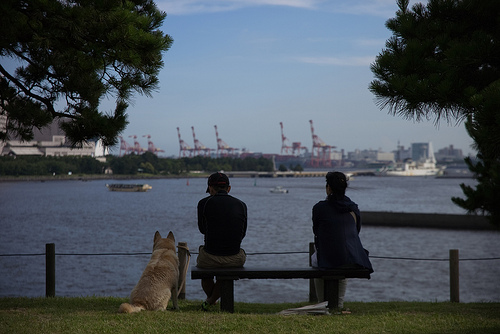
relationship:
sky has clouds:
[0, 0, 479, 158] [96, 2, 479, 160]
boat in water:
[379, 160, 440, 176] [0, 173, 499, 301]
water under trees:
[0, 173, 499, 301] [368, 36, 498, 220]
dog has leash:
[90, 190, 232, 319] [183, 255, 188, 294]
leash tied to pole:
[183, 255, 188, 294] [424, 200, 488, 320]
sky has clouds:
[183, 55, 297, 106] [302, 55, 372, 67]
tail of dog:
[115, 288, 155, 312] [124, 224, 206, 304]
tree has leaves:
[2, 0, 176, 165] [0, 2, 173, 98]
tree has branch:
[2, 0, 176, 165] [0, 62, 105, 131]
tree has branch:
[2, 0, 176, 165] [0, 39, 107, 96]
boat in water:
[384, 161, 441, 176] [0, 173, 499, 301]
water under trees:
[0, 173, 499, 301] [4, 11, 497, 221]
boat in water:
[361, 210, 497, 231] [373, 232, 472, 246]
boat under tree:
[361, 210, 497, 231] [365, 1, 498, 226]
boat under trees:
[379, 160, 440, 176] [0, 1, 175, 183]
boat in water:
[379, 160, 440, 176] [35, 191, 150, 232]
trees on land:
[368, 0, 498, 216] [360, 210, 499, 232]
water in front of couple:
[0, 173, 499, 301] [194, 167, 374, 308]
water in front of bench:
[0, 173, 499, 301] [187, 260, 374, 311]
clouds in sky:
[221, 11, 351, 88] [105, 9, 355, 130]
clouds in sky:
[271, 53, 380, 67] [130, 11, 427, 143]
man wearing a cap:
[198, 173, 242, 267] [186, 154, 235, 201]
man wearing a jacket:
[197, 173, 246, 311] [295, 196, 399, 298]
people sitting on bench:
[310, 171, 370, 267] [195, 272, 371, 306]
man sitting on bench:
[197, 173, 246, 311] [195, 272, 371, 306]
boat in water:
[107, 183, 153, 192] [0, 173, 499, 301]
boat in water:
[2, 96, 108, 163] [0, 173, 499, 301]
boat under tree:
[2, 96, 108, 163] [0, 1, 171, 149]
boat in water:
[432, 164, 479, 179] [0, 173, 499, 301]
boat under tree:
[432, 164, 479, 179] [365, 1, 498, 226]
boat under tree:
[432, 164, 479, 179] [0, 1, 171, 149]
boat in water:
[107, 183, 153, 192] [9, 165, 484, 315]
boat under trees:
[107, 183, 153, 192] [0, 2, 175, 149]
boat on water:
[107, 183, 153, 192] [15, 194, 172, 254]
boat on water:
[259, 178, 293, 199] [15, 194, 172, 254]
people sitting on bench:
[310, 171, 370, 315] [187, 260, 374, 311]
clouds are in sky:
[271, 53, 380, 67] [191, 12, 349, 127]